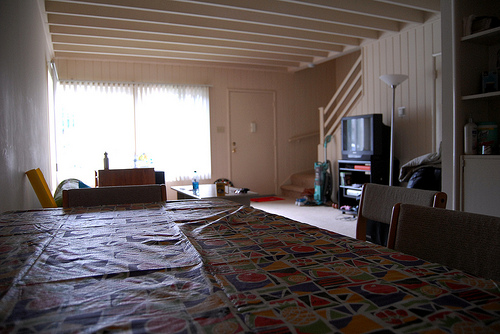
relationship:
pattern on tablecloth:
[365, 282, 397, 294] [3, 198, 498, 332]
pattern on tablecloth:
[332, 316, 384, 333] [3, 198, 498, 332]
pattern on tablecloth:
[247, 313, 283, 326] [3, 198, 498, 332]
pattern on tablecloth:
[282, 307, 317, 324] [3, 198, 498, 332]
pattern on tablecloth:
[374, 306, 409, 327] [3, 198, 498, 332]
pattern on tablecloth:
[317, 275, 352, 290] [3, 198, 498, 332]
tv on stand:
[342, 112, 390, 158] [335, 160, 398, 209]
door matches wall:
[230, 87, 276, 196] [279, 60, 336, 185]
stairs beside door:
[282, 167, 316, 198] [230, 87, 276, 196]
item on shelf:
[480, 70, 499, 95] [462, 92, 500, 99]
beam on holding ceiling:
[282, 1, 417, 25] [43, 1, 440, 58]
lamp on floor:
[380, 73, 409, 185] [250, 196, 358, 241]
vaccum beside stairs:
[313, 131, 331, 206] [282, 167, 316, 198]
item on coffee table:
[215, 181, 230, 196] [172, 183, 258, 207]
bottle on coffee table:
[192, 170, 198, 189] [172, 183, 258, 207]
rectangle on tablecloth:
[287, 282, 321, 294] [3, 198, 498, 332]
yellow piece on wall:
[28, 168, 57, 208] [0, 1, 57, 207]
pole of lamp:
[387, 84, 397, 186] [380, 73, 409, 185]